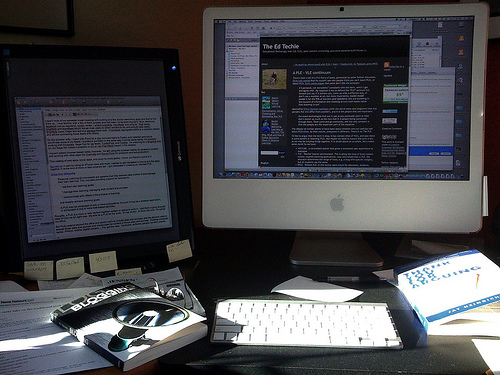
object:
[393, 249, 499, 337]
book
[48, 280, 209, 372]
book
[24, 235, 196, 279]
edge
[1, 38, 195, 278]
computer.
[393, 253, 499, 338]
white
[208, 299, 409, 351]
keyboard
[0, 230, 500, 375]
desk.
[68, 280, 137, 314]
blogging.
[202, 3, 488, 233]
white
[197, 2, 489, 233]
monitor.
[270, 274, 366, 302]
paper.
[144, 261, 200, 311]
pair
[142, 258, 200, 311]
glasses.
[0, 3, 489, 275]
two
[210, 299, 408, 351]
white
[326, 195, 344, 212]
logo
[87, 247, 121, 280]
notes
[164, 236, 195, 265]
bottom.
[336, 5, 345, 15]
camera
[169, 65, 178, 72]
light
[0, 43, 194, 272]
monitor.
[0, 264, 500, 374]
sun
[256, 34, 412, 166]
website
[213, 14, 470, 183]
screen.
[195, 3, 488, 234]
frame.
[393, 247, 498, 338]
blue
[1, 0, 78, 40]
frame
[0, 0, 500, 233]
wall.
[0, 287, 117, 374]
papers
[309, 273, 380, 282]
pen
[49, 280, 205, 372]
black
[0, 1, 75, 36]
picture